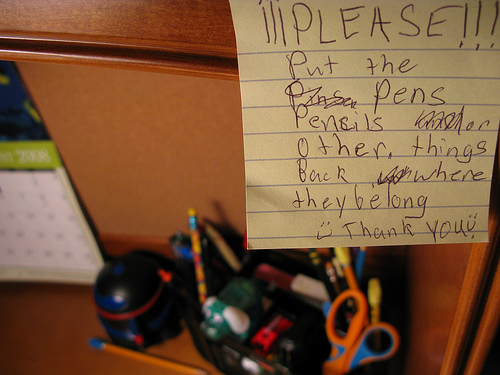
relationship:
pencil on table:
[115, 313, 186, 375] [11, 304, 80, 367]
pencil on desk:
[115, 313, 186, 375] [37, 277, 112, 368]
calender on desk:
[5, 33, 148, 273] [37, 277, 112, 368]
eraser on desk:
[359, 277, 388, 307] [37, 277, 112, 368]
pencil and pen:
[115, 313, 186, 375] [302, 249, 354, 322]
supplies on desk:
[154, 205, 399, 348] [37, 277, 112, 368]